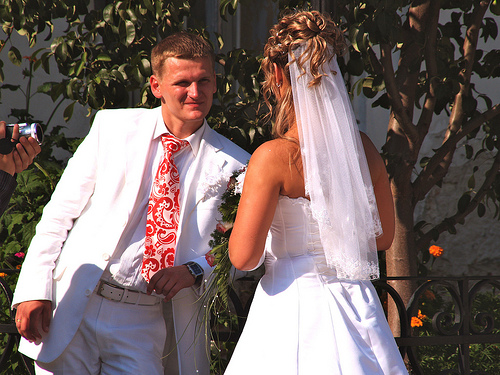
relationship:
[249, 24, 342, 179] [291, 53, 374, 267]
bride wearing veil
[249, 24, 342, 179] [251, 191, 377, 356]
bride wearing dress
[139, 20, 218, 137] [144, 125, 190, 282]
groom wearing necktie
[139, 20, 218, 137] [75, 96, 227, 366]
groom wearing suit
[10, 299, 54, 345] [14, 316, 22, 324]
hand with ring